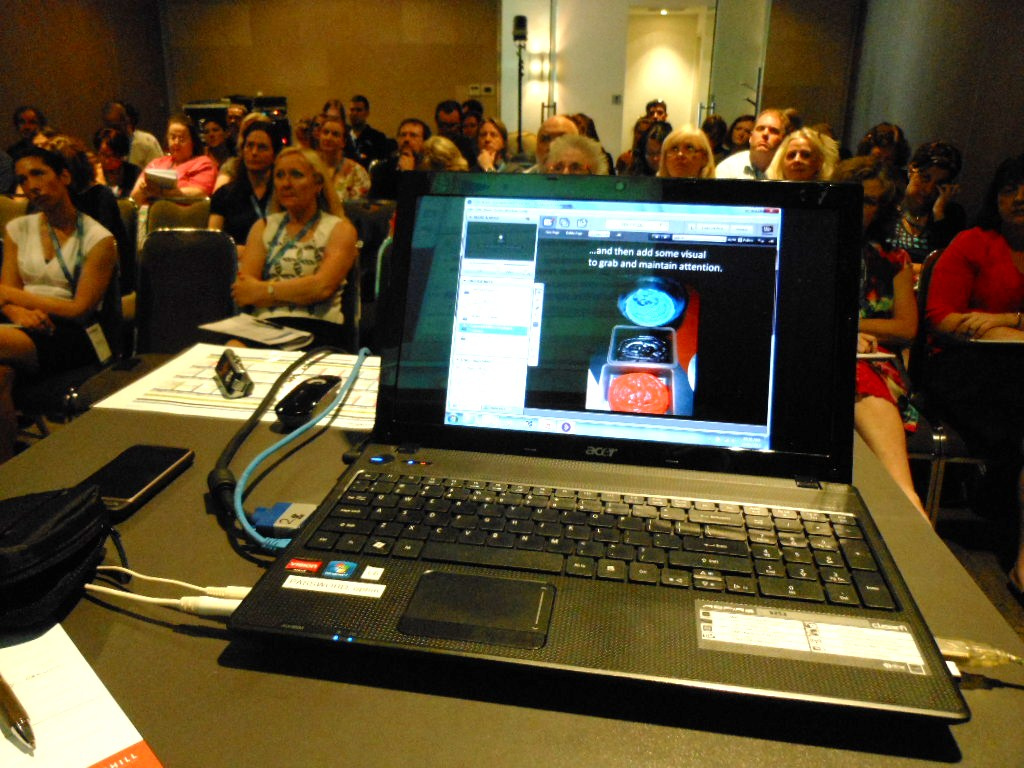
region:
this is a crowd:
[137, 92, 420, 293]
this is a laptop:
[304, 180, 865, 756]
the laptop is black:
[321, 379, 926, 689]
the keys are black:
[409, 449, 716, 545]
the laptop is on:
[433, 227, 769, 463]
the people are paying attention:
[38, 101, 353, 305]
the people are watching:
[111, 124, 505, 393]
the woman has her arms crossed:
[239, 160, 402, 370]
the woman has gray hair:
[193, 154, 359, 218]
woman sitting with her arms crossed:
[231, 141, 356, 350]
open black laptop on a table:
[225, 162, 975, 729]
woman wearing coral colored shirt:
[125, 110, 215, 208]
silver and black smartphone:
[68, 440, 192, 530]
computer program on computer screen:
[368, 165, 865, 485]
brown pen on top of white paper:
[0, 614, 169, 766]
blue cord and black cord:
[198, 338, 373, 554]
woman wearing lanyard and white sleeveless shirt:
[228, 135, 359, 350]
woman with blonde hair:
[236, 141, 357, 351]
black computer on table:
[409, 170, 994, 760]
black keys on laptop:
[327, 436, 900, 640]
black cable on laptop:
[213, 392, 274, 590]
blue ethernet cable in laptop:
[269, 374, 368, 581]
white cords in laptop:
[49, 544, 262, 655]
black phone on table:
[61, 412, 198, 511]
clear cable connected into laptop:
[947, 623, 1014, 704]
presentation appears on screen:
[397, 167, 885, 521]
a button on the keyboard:
[532, 512, 562, 567]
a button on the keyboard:
[670, 541, 690, 574]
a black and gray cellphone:
[70, 436, 198, 513]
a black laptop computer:
[228, 167, 975, 737]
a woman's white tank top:
[250, 203, 349, 325]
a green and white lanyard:
[38, 202, 86, 295]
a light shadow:
[633, 41, 682, 96]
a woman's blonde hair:
[653, 120, 721, 182]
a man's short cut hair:
[399, 114, 435, 143]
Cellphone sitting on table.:
[72, 442, 197, 522]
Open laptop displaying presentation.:
[224, 167, 972, 728]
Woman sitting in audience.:
[237, 143, 352, 359]